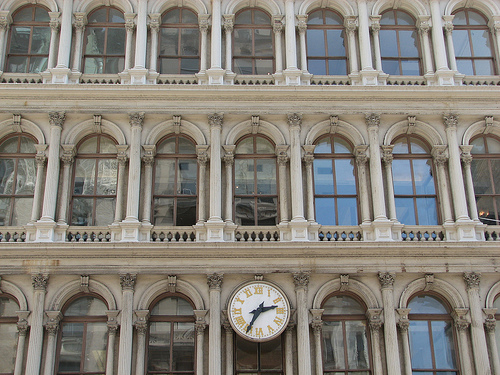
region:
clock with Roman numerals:
[226, 280, 289, 340]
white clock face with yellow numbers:
[228, 278, 292, 339]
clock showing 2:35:
[228, 280, 291, 342]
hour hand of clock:
[250, 304, 279, 316]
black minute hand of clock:
[242, 301, 265, 335]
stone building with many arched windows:
[0, 130, 496, 373]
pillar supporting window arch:
[301, 142, 319, 238]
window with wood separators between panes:
[304, 130, 362, 237]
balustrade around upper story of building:
[0, 222, 499, 242]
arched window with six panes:
[65, 130, 120, 233]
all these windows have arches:
[38, 95, 482, 244]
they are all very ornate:
[43, 113, 493, 238]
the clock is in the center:
[225, 270, 317, 353]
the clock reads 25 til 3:
[222, 275, 303, 354]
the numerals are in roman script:
[219, 270, 314, 366]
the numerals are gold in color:
[223, 277, 299, 347]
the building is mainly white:
[16, 6, 486, 371]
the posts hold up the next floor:
[107, 107, 343, 241]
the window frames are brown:
[143, 275, 210, 373]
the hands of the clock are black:
[235, 292, 324, 342]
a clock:
[210, 290, 277, 364]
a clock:
[267, 227, 324, 351]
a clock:
[197, 207, 325, 369]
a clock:
[181, 267, 299, 354]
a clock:
[220, 240, 277, 355]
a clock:
[191, 272, 256, 367]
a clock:
[241, 300, 285, 365]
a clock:
[247, 225, 309, 365]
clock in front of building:
[236, 281, 331, 356]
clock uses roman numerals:
[229, 289, 292, 331]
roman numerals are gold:
[242, 290, 289, 337]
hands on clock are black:
[256, 306, 284, 330]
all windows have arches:
[11, 13, 481, 340]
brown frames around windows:
[41, 138, 115, 244]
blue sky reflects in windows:
[312, 125, 365, 227]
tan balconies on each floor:
[191, 62, 428, 135]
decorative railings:
[155, 206, 292, 246]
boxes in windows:
[158, 41, 209, 103]